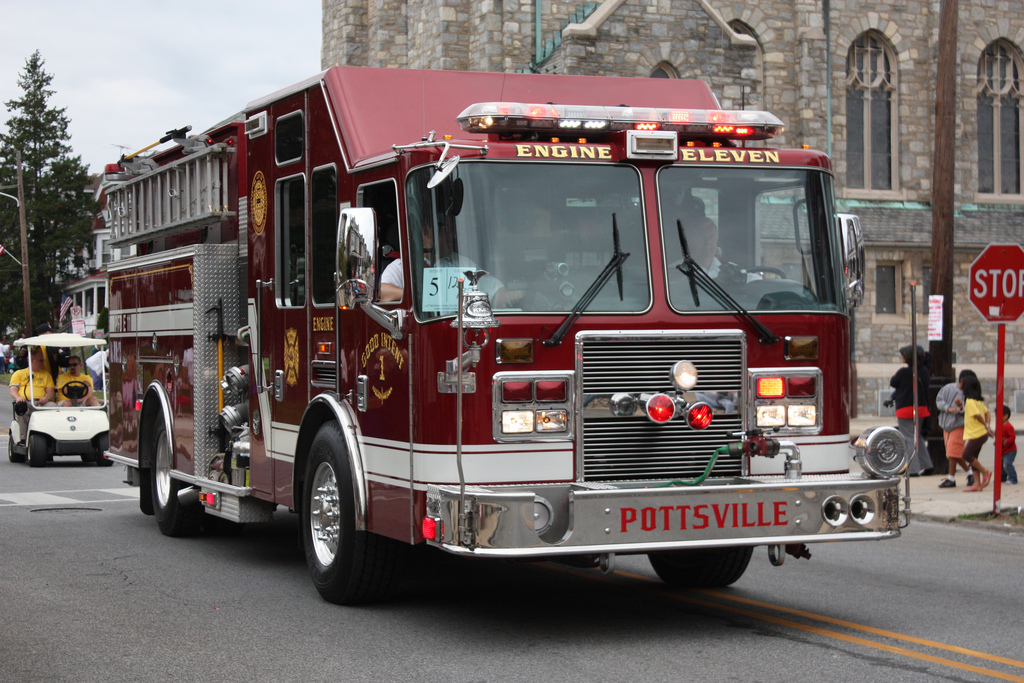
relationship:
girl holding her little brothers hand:
[952, 363, 987, 491] [984, 420, 993, 436]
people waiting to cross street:
[874, 335, 989, 487] [8, 422, 991, 678]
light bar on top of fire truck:
[457, 94, 784, 149] [92, 65, 918, 610]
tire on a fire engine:
[295, 413, 417, 606] [102, 66, 912, 607]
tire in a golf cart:
[23, 424, 58, 468] [8, 332, 115, 468]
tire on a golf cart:
[4, 417, 31, 461] [8, 332, 115, 468]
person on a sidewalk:
[892, 336, 932, 477] [900, 426, 989, 539]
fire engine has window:
[102, 66, 912, 607] [402, 158, 649, 314]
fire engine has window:
[102, 66, 912, 607] [266, 162, 316, 309]